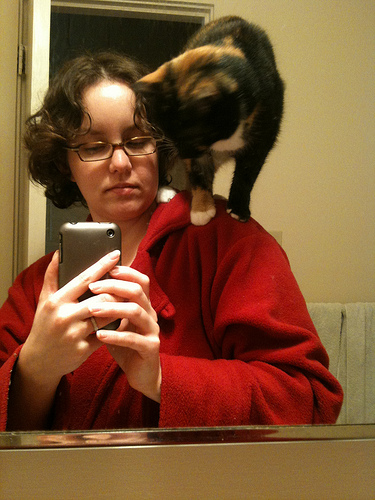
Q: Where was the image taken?
A: It was taken at the bathroom.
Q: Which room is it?
A: It is a bathroom.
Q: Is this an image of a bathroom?
A: Yes, it is showing a bathroom.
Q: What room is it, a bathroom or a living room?
A: It is a bathroom.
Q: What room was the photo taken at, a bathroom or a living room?
A: It was taken at a bathroom.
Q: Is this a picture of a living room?
A: No, the picture is showing a bathroom.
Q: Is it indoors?
A: Yes, it is indoors.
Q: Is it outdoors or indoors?
A: It is indoors.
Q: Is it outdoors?
A: No, it is indoors.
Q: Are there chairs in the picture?
A: No, there are no chairs.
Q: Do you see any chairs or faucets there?
A: No, there are no chairs or faucets.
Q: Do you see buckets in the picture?
A: No, there are no buckets.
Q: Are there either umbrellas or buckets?
A: No, there are no buckets or umbrellas.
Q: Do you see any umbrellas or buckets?
A: No, there are no buckets or umbrellas.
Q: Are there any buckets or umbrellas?
A: No, there are no buckets or umbrellas.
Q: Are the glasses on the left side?
A: Yes, the glasses are on the left of the image.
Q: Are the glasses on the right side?
A: No, the glasses are on the left of the image.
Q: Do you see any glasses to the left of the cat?
A: Yes, there are glasses to the left of the cat.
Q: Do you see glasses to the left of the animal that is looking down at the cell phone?
A: Yes, there are glasses to the left of the cat.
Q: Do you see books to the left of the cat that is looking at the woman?
A: No, there are glasses to the left of the cat.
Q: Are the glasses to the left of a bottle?
A: No, the glasses are to the left of a cat.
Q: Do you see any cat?
A: Yes, there is a cat.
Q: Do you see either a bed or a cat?
A: Yes, there is a cat.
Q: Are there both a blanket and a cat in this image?
A: No, there is a cat but no blankets.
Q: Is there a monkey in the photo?
A: No, there are no monkeys.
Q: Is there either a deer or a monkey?
A: No, there are no monkeys or deer.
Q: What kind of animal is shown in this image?
A: The animal is a cat.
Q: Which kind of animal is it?
A: The animal is a cat.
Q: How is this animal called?
A: That is a cat.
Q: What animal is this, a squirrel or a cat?
A: That is a cat.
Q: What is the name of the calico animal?
A: The animal is a cat.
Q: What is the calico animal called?
A: The animal is a cat.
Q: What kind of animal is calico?
A: The animal is a cat.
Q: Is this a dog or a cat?
A: This is a cat.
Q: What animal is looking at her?
A: The cat is looking at the woman.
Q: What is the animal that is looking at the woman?
A: The animal is a cat.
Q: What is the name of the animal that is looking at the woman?
A: The animal is a cat.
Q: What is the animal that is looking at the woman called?
A: The animal is a cat.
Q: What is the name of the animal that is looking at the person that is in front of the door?
A: The animal is a cat.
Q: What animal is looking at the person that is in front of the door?
A: The animal is a cat.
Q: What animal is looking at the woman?
A: The animal is a cat.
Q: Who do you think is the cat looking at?
A: The cat is looking at the woman.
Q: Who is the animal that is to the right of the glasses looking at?
A: The cat is looking at the woman.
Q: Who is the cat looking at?
A: The cat is looking at the woman.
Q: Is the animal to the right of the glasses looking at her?
A: Yes, the cat is looking at the woman.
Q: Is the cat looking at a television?
A: No, the cat is looking at the woman.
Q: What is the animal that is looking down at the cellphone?
A: The animal is a cat.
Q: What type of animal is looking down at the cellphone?
A: The animal is a cat.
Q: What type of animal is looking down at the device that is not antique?
A: The animal is a cat.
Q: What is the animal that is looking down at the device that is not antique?
A: The animal is a cat.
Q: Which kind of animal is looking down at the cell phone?
A: The animal is a cat.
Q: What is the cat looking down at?
A: The cat is looking down at the cellphone.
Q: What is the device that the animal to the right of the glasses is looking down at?
A: The device is a cell phone.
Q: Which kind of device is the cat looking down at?
A: The cat is looking down at the cellphone.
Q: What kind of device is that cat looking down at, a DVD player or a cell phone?
A: The cat is looking down at a cell phone.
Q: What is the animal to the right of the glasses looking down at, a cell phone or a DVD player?
A: The cat is looking down at a cell phone.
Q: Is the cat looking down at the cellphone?
A: Yes, the cat is looking down at the cellphone.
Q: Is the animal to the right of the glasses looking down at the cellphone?
A: Yes, the cat is looking down at the cellphone.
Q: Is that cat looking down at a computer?
A: No, the cat is looking down at the cellphone.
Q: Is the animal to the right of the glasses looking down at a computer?
A: No, the cat is looking down at the cellphone.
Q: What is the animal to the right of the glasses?
A: The animal is a cat.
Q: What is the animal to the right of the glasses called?
A: The animal is a cat.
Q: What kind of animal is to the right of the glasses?
A: The animal is a cat.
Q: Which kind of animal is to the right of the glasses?
A: The animal is a cat.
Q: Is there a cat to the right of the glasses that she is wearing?
A: Yes, there is a cat to the right of the glasses.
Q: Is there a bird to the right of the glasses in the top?
A: No, there is a cat to the right of the glasses.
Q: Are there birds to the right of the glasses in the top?
A: No, there is a cat to the right of the glasses.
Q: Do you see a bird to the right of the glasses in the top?
A: No, there is a cat to the right of the glasses.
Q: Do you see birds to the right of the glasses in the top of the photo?
A: No, there is a cat to the right of the glasses.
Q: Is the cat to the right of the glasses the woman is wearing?
A: Yes, the cat is to the right of the glasses.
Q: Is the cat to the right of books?
A: No, the cat is to the right of the glasses.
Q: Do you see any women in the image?
A: Yes, there is a woman.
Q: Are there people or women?
A: Yes, there is a woman.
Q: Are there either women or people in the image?
A: Yes, there is a woman.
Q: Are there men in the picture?
A: No, there are no men.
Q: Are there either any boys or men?
A: No, there are no men or boys.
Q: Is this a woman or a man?
A: This is a woman.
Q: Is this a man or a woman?
A: This is a woman.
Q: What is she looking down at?
A: The woman is looking down at the mobile phone.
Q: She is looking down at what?
A: The woman is looking down at the mobile phone.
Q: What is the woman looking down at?
A: The woman is looking down at the mobile phone.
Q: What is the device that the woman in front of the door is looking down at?
A: The device is a cell phone.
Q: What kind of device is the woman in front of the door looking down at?
A: The woman is looking down at the mobile phone.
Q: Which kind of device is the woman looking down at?
A: The woman is looking down at the mobile phone.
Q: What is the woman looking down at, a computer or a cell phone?
A: The woman is looking down at a cell phone.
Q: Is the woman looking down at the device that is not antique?
A: Yes, the woman is looking down at the mobile phone.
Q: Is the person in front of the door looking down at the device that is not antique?
A: Yes, the woman is looking down at the mobile phone.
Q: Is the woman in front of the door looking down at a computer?
A: No, the woman is looking down at the mobile phone.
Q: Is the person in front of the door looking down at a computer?
A: No, the woman is looking down at the mobile phone.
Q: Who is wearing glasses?
A: The woman is wearing glasses.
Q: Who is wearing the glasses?
A: The woman is wearing glasses.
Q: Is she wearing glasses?
A: Yes, the woman is wearing glasses.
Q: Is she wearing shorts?
A: No, the woman is wearing glasses.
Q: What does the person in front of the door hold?
A: The woman holds the cell phone.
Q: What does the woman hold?
A: The woman holds the cell phone.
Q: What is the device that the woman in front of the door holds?
A: The device is a cell phone.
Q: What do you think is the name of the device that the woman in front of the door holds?
A: The device is a cell phone.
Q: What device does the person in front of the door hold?
A: The woman holds the cell phone.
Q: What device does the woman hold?
A: The woman holds the cell phone.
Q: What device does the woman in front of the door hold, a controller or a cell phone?
A: The woman holds a cell phone.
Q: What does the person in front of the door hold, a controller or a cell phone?
A: The woman holds a cell phone.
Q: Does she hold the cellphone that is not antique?
A: Yes, the woman holds the cellphone.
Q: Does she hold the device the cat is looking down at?
A: Yes, the woman holds the cellphone.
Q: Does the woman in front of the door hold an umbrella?
A: No, the woman holds the cellphone.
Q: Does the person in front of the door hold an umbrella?
A: No, the woman holds the cellphone.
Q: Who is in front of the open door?
A: The woman is in front of the door.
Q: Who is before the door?
A: The woman is in front of the door.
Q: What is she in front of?
A: The woman is in front of the door.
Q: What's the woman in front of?
A: The woman is in front of the door.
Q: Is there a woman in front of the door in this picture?
A: Yes, there is a woman in front of the door.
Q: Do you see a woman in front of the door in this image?
A: Yes, there is a woman in front of the door.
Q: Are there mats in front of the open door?
A: No, there is a woman in front of the door.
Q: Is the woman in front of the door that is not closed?
A: Yes, the woman is in front of the door.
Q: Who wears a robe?
A: The woman wears a robe.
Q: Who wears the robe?
A: The woman wears a robe.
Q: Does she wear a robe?
A: Yes, the woman wears a robe.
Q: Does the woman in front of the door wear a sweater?
A: No, the woman wears a robe.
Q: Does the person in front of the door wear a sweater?
A: No, the woman wears a robe.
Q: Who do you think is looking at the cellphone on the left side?
A: The woman is looking at the cell phone.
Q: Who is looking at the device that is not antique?
A: The woman is looking at the cell phone.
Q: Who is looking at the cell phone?
A: The woman is looking at the cell phone.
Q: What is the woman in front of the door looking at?
A: The woman is looking at the cell phone.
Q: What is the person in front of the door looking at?
A: The woman is looking at the cell phone.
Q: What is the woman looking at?
A: The woman is looking at the cell phone.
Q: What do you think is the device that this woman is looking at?
A: The device is a cell phone.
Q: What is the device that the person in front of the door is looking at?
A: The device is a cell phone.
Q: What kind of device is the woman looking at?
A: The woman is looking at the cell phone.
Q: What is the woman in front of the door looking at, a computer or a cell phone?
A: The woman is looking at a cell phone.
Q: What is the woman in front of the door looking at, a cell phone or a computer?
A: The woman is looking at a cell phone.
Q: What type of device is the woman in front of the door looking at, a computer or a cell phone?
A: The woman is looking at a cell phone.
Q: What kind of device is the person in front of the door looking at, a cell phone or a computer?
A: The woman is looking at a cell phone.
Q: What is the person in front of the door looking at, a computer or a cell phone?
A: The woman is looking at a cell phone.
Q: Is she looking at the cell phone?
A: Yes, the woman is looking at the cell phone.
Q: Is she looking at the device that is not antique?
A: Yes, the woman is looking at the cell phone.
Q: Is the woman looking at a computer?
A: No, the woman is looking at the cell phone.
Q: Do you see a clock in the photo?
A: No, there are no clocks.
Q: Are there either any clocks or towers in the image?
A: No, there are no clocks or towers.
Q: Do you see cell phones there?
A: Yes, there is a cell phone.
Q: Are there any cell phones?
A: Yes, there is a cell phone.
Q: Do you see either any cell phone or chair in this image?
A: Yes, there is a cell phone.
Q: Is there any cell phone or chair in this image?
A: Yes, there is a cell phone.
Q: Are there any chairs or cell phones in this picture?
A: Yes, there is a cell phone.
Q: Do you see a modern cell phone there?
A: Yes, there is a modern cell phone.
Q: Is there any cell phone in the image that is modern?
A: Yes, there is a cell phone that is modern.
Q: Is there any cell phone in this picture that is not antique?
A: Yes, there is an modern cell phone.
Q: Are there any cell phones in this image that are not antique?
A: Yes, there is an modern cell phone.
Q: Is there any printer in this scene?
A: No, there are no printers.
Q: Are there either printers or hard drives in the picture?
A: No, there are no printers or hard drives.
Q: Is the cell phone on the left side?
A: Yes, the cell phone is on the left of the image.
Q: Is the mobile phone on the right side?
A: No, the mobile phone is on the left of the image.